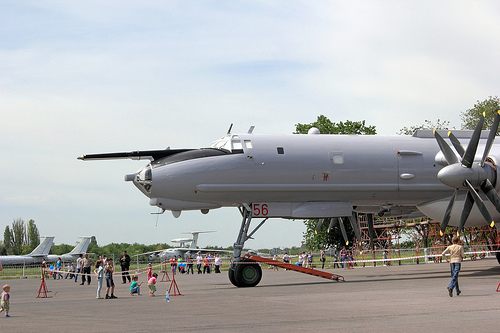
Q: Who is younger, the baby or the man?
A: The baby is younger than the man.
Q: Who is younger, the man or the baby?
A: The baby is younger than the man.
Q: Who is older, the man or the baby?
A: The man is older than the baby.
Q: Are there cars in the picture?
A: No, there are no cars.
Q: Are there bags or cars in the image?
A: No, there are no cars or bags.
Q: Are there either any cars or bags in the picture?
A: No, there are no cars or bags.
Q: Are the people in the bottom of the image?
A: Yes, the people are in the bottom of the image.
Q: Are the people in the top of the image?
A: No, the people are in the bottom of the image.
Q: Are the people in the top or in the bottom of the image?
A: The people are in the bottom of the image.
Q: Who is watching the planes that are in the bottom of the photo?
A: The people are watching the planes.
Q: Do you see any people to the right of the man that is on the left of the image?
A: Yes, there are people to the right of the man.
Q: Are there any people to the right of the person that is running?
A: Yes, there are people to the right of the man.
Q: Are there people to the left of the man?
A: No, the people are to the right of the man.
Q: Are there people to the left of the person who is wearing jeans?
A: No, the people are to the right of the man.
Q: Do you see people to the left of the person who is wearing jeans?
A: No, the people are to the right of the man.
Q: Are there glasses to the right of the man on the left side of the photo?
A: No, there are people to the right of the man.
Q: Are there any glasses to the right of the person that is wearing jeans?
A: No, there are people to the right of the man.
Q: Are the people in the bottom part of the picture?
A: Yes, the people are in the bottom of the image.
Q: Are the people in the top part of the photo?
A: No, the people are in the bottom of the image.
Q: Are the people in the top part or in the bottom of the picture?
A: The people are in the bottom of the image.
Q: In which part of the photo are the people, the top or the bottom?
A: The people are in the bottom of the image.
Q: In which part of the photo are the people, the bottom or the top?
A: The people are in the bottom of the image.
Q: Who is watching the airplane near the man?
A: The people are watching the airplane.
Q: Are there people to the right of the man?
A: Yes, there are people to the right of the man.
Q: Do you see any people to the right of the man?
A: Yes, there are people to the right of the man.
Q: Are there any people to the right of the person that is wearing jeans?
A: Yes, there are people to the right of the man.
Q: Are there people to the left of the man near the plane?
A: No, the people are to the right of the man.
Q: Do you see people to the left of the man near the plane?
A: No, the people are to the right of the man.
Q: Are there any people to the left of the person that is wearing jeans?
A: No, the people are to the right of the man.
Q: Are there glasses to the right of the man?
A: No, there are people to the right of the man.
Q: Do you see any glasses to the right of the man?
A: No, there are people to the right of the man.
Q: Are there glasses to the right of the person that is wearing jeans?
A: No, there are people to the right of the man.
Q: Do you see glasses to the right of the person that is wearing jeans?
A: No, there are people to the right of the man.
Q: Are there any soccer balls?
A: No, there are no soccer balls.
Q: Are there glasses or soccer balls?
A: No, there are no soccer balls or glasses.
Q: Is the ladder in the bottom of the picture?
A: Yes, the ladder is in the bottom of the image.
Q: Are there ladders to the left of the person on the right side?
A: Yes, there is a ladder to the left of the person.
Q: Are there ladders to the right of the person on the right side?
A: No, the ladder is to the left of the person.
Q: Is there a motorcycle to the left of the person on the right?
A: No, there is a ladder to the left of the person.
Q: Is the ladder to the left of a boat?
A: No, the ladder is to the left of a person.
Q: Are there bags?
A: No, there are no bags.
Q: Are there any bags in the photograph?
A: No, there are no bags.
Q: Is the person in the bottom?
A: Yes, the person is in the bottom of the image.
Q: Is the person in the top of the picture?
A: No, the person is in the bottom of the image.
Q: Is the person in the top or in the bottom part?
A: The person is in the bottom of the image.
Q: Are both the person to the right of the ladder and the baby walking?
A: Yes, both the person and the baby are walking.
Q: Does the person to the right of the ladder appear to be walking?
A: Yes, the person is walking.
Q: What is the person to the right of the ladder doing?
A: The person is walking.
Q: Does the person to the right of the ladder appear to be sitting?
A: No, the person is walking.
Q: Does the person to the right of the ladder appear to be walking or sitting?
A: The person is walking.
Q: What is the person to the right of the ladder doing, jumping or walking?
A: The person is walking.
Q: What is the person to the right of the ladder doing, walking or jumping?
A: The person is walking.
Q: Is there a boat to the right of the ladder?
A: No, there is a person to the right of the ladder.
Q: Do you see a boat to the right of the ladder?
A: No, there is a person to the right of the ladder.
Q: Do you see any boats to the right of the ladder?
A: No, there is a person to the right of the ladder.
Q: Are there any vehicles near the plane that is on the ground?
A: No, there is a person near the airplane.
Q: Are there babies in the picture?
A: Yes, there is a baby.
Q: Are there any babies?
A: Yes, there is a baby.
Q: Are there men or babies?
A: Yes, there is a baby.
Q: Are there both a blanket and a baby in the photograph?
A: No, there is a baby but no blankets.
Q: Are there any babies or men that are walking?
A: Yes, the baby is walking.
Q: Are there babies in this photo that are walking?
A: Yes, there is a baby that is walking.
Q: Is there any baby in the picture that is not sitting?
A: Yes, there is a baby that is walking.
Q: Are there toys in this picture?
A: No, there are no toys.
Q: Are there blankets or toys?
A: No, there are no toys or blankets.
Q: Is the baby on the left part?
A: Yes, the baby is on the left of the image.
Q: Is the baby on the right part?
A: No, the baby is on the left of the image.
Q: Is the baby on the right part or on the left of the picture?
A: The baby is on the left of the image.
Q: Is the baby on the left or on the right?
A: The baby is on the left of the image.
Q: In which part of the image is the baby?
A: The baby is on the left of the image.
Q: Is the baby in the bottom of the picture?
A: Yes, the baby is in the bottom of the image.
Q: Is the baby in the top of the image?
A: No, the baby is in the bottom of the image.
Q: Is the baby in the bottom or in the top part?
A: The baby is in the bottom of the image.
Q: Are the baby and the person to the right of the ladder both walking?
A: Yes, both the baby and the person are walking.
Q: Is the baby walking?
A: Yes, the baby is walking.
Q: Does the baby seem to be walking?
A: Yes, the baby is walking.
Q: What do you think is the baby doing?
A: The baby is walking.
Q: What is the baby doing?
A: The baby is walking.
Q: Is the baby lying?
A: No, the baby is walking.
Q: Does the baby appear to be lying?
A: No, the baby is walking.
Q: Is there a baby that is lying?
A: No, there is a baby but he is walking.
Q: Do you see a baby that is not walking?
A: No, there is a baby but he is walking.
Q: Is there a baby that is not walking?
A: No, there is a baby but he is walking.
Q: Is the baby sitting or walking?
A: The baby is walking.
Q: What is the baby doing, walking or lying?
A: The baby is walking.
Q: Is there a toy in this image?
A: No, there are no toys.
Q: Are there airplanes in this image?
A: Yes, there is an airplane.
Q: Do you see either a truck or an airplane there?
A: Yes, there is an airplane.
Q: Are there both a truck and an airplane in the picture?
A: No, there is an airplane but no trucks.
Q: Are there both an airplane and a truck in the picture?
A: No, there is an airplane but no trucks.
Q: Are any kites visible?
A: No, there are no kites.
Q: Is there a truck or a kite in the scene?
A: No, there are no kites or trucks.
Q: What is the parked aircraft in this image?
A: The aircraft is an airplane.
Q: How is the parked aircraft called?
A: The aircraft is an airplane.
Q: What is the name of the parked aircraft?
A: The aircraft is an airplane.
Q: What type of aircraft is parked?
A: The aircraft is an airplane.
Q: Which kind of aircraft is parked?
A: The aircraft is an airplane.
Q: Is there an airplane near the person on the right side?
A: Yes, there is an airplane near the person.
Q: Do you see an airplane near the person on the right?
A: Yes, there is an airplane near the person.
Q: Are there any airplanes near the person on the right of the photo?
A: Yes, there is an airplane near the person.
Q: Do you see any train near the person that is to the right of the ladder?
A: No, there is an airplane near the person.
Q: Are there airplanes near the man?
A: Yes, there is an airplane near the man.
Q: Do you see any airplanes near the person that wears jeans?
A: Yes, there is an airplane near the man.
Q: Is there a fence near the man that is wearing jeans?
A: No, there is an airplane near the man.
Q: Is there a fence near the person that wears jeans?
A: No, there is an airplane near the man.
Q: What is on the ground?
A: The plane is on the ground.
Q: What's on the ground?
A: The plane is on the ground.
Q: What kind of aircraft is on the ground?
A: The aircraft is an airplane.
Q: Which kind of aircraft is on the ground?
A: The aircraft is an airplane.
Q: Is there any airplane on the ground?
A: Yes, there is an airplane on the ground.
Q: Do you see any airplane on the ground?
A: Yes, there is an airplane on the ground.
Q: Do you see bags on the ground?
A: No, there is an airplane on the ground.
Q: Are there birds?
A: No, there are no birds.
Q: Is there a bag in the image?
A: No, there are no bags.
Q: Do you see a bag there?
A: No, there are no bags.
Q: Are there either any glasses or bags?
A: No, there are no bags or glasses.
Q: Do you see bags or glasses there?
A: No, there are no bags or glasses.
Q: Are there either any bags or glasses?
A: No, there are no bags or glasses.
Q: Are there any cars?
A: No, there are no cars.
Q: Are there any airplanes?
A: Yes, there are airplanes.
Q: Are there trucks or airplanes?
A: Yes, there are airplanes.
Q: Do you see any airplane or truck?
A: Yes, there are airplanes.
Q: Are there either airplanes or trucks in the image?
A: Yes, there are airplanes.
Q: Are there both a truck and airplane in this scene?
A: No, there are airplanes but no trucks.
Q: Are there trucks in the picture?
A: No, there are no trucks.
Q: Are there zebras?
A: No, there are no zebras.